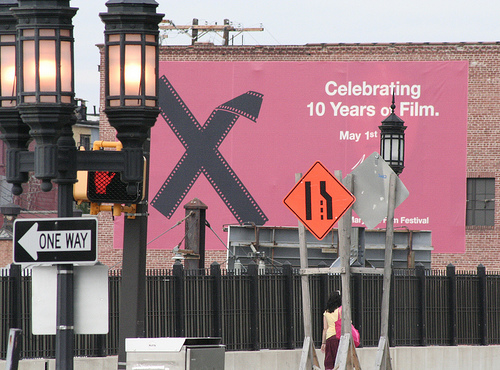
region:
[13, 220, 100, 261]
A one way sign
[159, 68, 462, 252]
A pink advertisement with an x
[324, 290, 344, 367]
A woman is walking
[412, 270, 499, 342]
A black fence along the street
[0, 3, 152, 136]
A cluster of three lights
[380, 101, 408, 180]
One light is off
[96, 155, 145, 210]
A pedestrian do not walk symbol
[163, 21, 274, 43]
Power lines on a post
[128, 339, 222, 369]
A silver box sits in the street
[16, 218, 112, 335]
Two signs on a post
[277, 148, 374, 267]
Orange sign on a post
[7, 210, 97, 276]
Black and white one way sign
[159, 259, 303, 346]
Fence surrounding the street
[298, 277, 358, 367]
Woman standing on the sidewalk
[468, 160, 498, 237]
Window on the side of the building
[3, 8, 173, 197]
Huge street light by the road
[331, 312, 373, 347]
Woman holding a pink purse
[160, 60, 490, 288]
Huge banner on the side of the building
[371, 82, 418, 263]
Tall street lamp on sidewalk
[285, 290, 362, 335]
Woman has dark hair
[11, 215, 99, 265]
one way sign pointing left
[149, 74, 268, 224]
painted film strip in the shape of an x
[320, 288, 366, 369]
woman with a large pink bag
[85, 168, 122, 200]
a red hand lit up on a sign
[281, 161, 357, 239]
an orange triangle sign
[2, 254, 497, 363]
a black iron fence along the sidewalk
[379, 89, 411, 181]
top part of a street light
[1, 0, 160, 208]
Three large street lamps that are on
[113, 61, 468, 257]
pink billboard on side of brick building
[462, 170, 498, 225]
a dark tinted window on the building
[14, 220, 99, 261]
Directional street signt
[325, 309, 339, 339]
woman wearing yellow shirt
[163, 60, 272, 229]
Film strips on billboard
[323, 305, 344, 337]
woman holding pink purse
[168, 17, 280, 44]
electrical lines behind building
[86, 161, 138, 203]
A walking signal barely visible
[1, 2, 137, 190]
Older style lantern street lights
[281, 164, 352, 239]
yellow traffic sign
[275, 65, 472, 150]
pink billboard with writing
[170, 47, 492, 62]
brick building behind billboard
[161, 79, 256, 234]
large x on sign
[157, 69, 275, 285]
large x made out of film pieces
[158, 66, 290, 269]
large x on wall of building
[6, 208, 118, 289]
one way road sign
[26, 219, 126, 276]
one way sign pointing left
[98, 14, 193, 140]
lit up street lights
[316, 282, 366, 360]
woman walkng away from camera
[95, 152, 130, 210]
red hand on street sign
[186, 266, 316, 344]
long metal brown fence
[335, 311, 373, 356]
large over sized purse on woman's shoulder